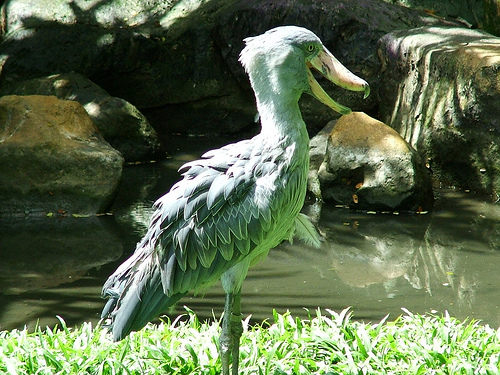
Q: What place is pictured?
A: It is a pond.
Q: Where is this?
A: This is at the pond.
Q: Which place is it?
A: It is a pond.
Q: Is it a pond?
A: Yes, it is a pond.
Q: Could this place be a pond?
A: Yes, it is a pond.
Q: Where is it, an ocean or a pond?
A: It is a pond.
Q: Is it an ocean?
A: No, it is a pond.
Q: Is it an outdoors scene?
A: Yes, it is outdoors.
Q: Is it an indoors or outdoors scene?
A: It is outdoors.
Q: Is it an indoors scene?
A: No, it is outdoors.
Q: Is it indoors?
A: No, it is outdoors.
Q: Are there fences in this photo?
A: No, there are no fences.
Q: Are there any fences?
A: No, there are no fences.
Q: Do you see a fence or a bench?
A: No, there are no fences or benches.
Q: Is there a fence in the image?
A: No, there are no fences.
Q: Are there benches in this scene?
A: No, there are no benches.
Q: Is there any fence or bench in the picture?
A: No, there are no benches or fences.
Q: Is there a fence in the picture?
A: No, there are no fences.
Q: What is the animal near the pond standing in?
A: The animal is standing in the grass.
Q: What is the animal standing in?
A: The animal is standing in the grass.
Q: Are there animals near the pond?
A: Yes, there is an animal near the pond.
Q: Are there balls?
A: No, there are no balls.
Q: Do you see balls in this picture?
A: No, there are no balls.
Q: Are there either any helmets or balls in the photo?
A: No, there are no balls or helmets.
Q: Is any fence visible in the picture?
A: No, there are no fences.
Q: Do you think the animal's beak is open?
A: Yes, the beak is open.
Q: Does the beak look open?
A: Yes, the beak is open.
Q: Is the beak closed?
A: No, the beak is open.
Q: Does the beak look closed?
A: No, the beak is open.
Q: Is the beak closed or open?
A: The beak is open.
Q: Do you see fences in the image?
A: No, there are no fences.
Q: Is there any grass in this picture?
A: Yes, there is grass.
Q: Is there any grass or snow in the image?
A: Yes, there is grass.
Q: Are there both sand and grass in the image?
A: No, there is grass but no sand.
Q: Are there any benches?
A: No, there are no benches.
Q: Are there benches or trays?
A: No, there are no benches or trays.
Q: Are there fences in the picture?
A: No, there are no fences.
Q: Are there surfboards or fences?
A: No, there are no fences or surfboards.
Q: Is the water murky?
A: Yes, the water is murky.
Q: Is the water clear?
A: No, the water is murky.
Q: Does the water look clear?
A: No, the water is murky.